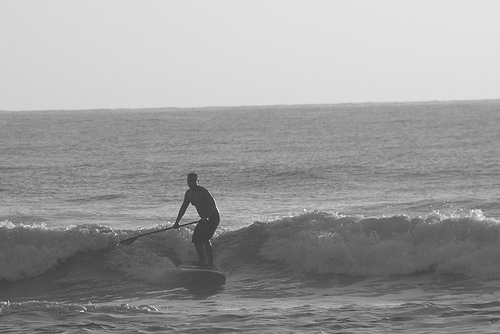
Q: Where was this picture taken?
A: The ocean.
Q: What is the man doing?
A: Surfing.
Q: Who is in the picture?
A: A man.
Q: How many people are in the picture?
A: One.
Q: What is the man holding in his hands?
A: Paddle.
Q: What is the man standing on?
A: Surfboard.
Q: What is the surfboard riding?
A: A wave.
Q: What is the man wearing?
A: Shorts.